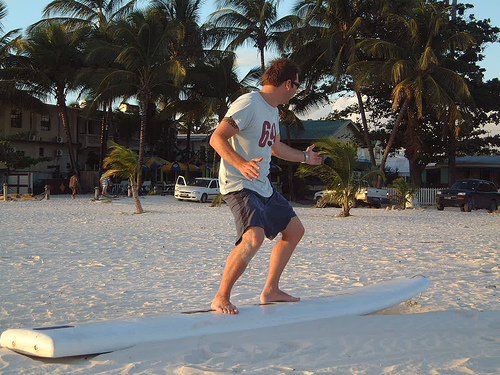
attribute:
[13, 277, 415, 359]
surfboard — white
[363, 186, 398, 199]
taillights — engaged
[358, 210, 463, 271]
sand — white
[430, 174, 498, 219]
black suv — parked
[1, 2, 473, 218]
palms — bushy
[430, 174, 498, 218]
car — black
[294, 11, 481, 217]
tree — large, green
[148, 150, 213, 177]
umbrellas — orange and blue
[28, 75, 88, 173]
house — large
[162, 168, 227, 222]
door — open, car door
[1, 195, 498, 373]
sand — white, clean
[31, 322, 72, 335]
design — black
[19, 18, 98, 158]
tree — shaded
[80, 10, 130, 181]
tree — shaded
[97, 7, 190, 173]
tree — shaded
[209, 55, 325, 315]
man — barefoot